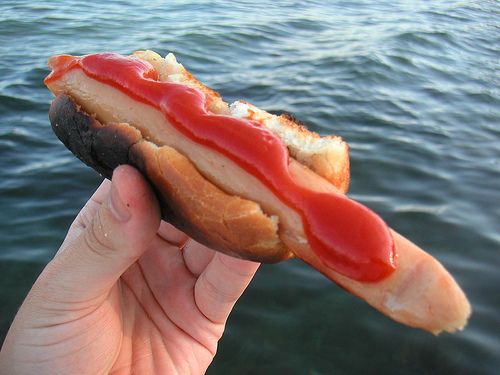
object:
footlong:
[42, 49, 473, 337]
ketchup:
[47, 53, 394, 284]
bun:
[48, 47, 351, 265]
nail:
[102, 178, 132, 226]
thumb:
[47, 160, 164, 304]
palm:
[112, 257, 196, 375]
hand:
[2, 169, 262, 372]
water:
[0, 0, 498, 370]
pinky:
[193, 250, 266, 328]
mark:
[383, 258, 437, 314]